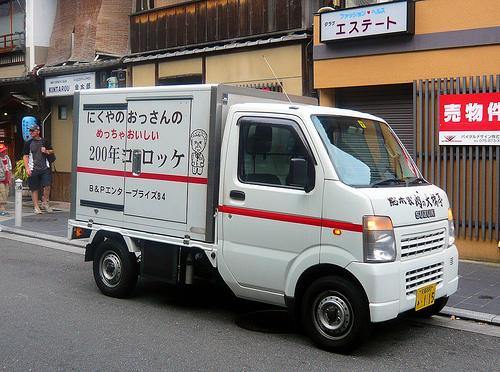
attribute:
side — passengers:
[214, 70, 385, 353]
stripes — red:
[60, 155, 216, 199]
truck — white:
[59, 49, 467, 354]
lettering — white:
[441, 95, 484, 131]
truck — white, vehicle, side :
[63, 71, 478, 355]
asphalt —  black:
[5, 220, 412, 366]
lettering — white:
[434, 96, 460, 126]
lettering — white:
[463, 100, 484, 123]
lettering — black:
[327, 21, 345, 37]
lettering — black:
[344, 17, 359, 33]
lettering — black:
[356, 17, 374, 38]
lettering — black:
[374, 13, 397, 35]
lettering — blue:
[339, 10, 399, 19]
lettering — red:
[332, 16, 403, 43]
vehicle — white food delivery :
[64, 78, 472, 356]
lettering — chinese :
[68, 95, 187, 204]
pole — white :
[8, 170, 26, 228]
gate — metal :
[407, 68, 483, 239]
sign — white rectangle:
[324, 11, 413, 43]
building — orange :
[313, 10, 484, 263]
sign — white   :
[432, 79, 484, 143]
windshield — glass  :
[315, 108, 425, 186]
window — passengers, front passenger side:
[232, 115, 323, 217]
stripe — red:
[73, 157, 365, 239]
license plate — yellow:
[410, 282, 443, 314]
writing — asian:
[87, 126, 165, 145]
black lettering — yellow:
[86, 109, 188, 127]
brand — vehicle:
[411, 208, 441, 221]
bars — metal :
[119, 2, 314, 38]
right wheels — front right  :
[304, 274, 373, 346]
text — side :
[84, 106, 200, 131]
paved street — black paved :
[2, 228, 499, 366]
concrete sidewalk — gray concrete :
[6, 190, 497, 336]